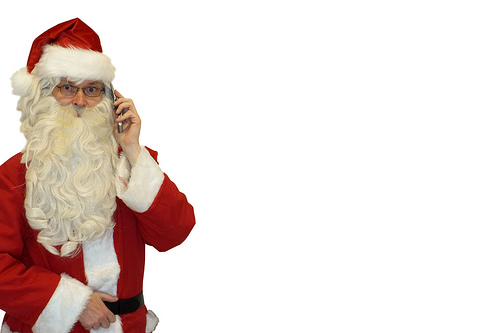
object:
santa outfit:
[0, 20, 195, 332]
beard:
[15, 77, 119, 257]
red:
[27, 19, 101, 71]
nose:
[74, 88, 87, 108]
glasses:
[56, 84, 104, 97]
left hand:
[112, 91, 140, 145]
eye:
[64, 86, 71, 91]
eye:
[87, 88, 95, 92]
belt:
[103, 291, 144, 314]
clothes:
[0, 14, 193, 333]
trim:
[36, 48, 114, 79]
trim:
[115, 147, 163, 212]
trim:
[30, 271, 88, 333]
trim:
[81, 238, 121, 332]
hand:
[78, 291, 119, 328]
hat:
[10, 17, 114, 95]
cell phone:
[113, 94, 124, 132]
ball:
[12, 68, 32, 94]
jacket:
[0, 146, 196, 333]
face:
[53, 80, 104, 108]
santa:
[0, 17, 196, 332]